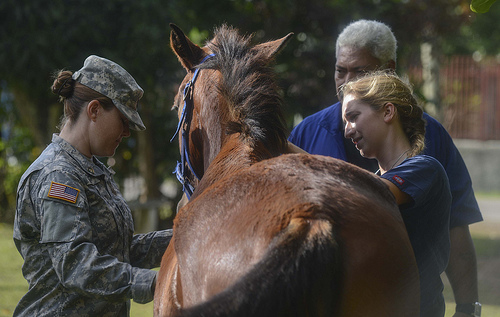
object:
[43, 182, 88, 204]
flag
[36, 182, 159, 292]
arm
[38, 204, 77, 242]
patch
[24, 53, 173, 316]
woman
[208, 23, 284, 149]
mane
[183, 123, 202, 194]
reins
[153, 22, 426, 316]
horse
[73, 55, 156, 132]
hat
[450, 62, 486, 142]
fence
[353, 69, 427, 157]
hair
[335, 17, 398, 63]
hair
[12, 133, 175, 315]
uniform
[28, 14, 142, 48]
trees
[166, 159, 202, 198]
halter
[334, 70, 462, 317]
woman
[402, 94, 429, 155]
braid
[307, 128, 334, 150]
blue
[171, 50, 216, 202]
bridle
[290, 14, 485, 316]
man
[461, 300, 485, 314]
watch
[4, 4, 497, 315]
photo